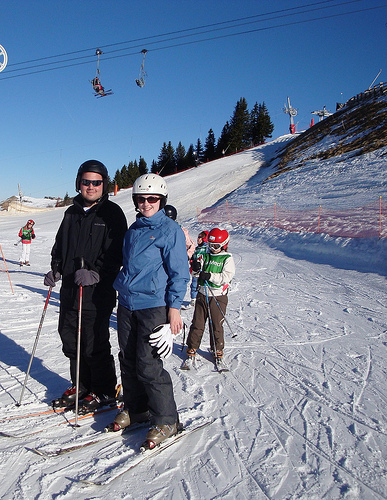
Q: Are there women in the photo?
A: Yes, there is a woman.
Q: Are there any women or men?
A: Yes, there is a woman.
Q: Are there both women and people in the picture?
A: Yes, there are both a woman and a person.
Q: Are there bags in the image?
A: No, there are no bags.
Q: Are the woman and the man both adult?
A: Yes, both the woman and the man are adult.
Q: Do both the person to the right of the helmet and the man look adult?
A: Yes, both the woman and the man are adult.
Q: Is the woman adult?
A: Yes, the woman is adult.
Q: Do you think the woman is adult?
A: Yes, the woman is adult.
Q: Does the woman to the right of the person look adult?
A: Yes, the woman is adult.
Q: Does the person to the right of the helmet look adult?
A: Yes, the woman is adult.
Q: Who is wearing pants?
A: The woman is wearing pants.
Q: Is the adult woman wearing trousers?
A: Yes, the woman is wearing trousers.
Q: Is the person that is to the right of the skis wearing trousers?
A: Yes, the woman is wearing trousers.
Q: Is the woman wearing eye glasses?
A: No, the woman is wearing trousers.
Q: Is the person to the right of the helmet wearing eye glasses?
A: No, the woman is wearing trousers.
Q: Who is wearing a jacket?
A: The woman is wearing a jacket.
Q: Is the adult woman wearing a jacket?
A: Yes, the woman is wearing a jacket.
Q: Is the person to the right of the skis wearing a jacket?
A: Yes, the woman is wearing a jacket.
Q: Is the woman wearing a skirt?
A: No, the woman is wearing a jacket.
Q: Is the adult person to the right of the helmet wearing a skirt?
A: No, the woman is wearing a jacket.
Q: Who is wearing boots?
A: The woman is wearing boots.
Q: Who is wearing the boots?
A: The woman is wearing boots.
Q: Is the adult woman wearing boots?
A: Yes, the woman is wearing boots.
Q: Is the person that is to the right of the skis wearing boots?
A: Yes, the woman is wearing boots.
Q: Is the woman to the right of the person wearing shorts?
A: No, the woman is wearing boots.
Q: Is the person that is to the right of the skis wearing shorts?
A: No, the woman is wearing boots.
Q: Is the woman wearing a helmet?
A: Yes, the woman is wearing a helmet.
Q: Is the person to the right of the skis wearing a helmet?
A: Yes, the woman is wearing a helmet.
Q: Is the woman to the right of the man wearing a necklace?
A: No, the woman is wearing a helmet.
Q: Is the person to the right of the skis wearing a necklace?
A: No, the woman is wearing a helmet.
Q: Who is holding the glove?
A: The woman is holding the glove.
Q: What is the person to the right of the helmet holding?
A: The woman is holding the glove.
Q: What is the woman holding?
A: The woman is holding the glove.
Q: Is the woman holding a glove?
A: Yes, the woman is holding a glove.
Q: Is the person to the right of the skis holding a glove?
A: Yes, the woman is holding a glove.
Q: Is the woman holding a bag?
A: No, the woman is holding a glove.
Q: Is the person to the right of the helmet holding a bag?
A: No, the woman is holding a glove.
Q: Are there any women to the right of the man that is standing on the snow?
A: Yes, there is a woman to the right of the man.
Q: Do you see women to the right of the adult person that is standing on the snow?
A: Yes, there is a woman to the right of the man.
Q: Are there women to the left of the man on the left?
A: No, the woman is to the right of the man.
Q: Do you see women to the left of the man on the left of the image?
A: No, the woman is to the right of the man.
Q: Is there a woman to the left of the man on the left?
A: No, the woman is to the right of the man.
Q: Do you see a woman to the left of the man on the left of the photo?
A: No, the woman is to the right of the man.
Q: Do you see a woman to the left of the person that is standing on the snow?
A: No, the woman is to the right of the man.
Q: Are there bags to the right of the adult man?
A: No, there is a woman to the right of the man.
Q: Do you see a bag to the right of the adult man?
A: No, there is a woman to the right of the man.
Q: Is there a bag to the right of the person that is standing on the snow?
A: No, there is a woman to the right of the man.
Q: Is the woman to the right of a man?
A: Yes, the woman is to the right of a man.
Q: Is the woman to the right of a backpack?
A: No, the woman is to the right of a man.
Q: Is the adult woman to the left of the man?
A: No, the woman is to the right of the man.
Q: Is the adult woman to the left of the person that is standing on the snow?
A: No, the woman is to the right of the man.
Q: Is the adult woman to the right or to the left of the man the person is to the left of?
A: The woman is to the right of the man.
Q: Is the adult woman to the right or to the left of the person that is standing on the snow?
A: The woman is to the right of the man.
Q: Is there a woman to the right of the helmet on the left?
A: Yes, there is a woman to the right of the helmet.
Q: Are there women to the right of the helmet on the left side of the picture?
A: Yes, there is a woman to the right of the helmet.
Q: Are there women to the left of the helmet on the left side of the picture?
A: No, the woman is to the right of the helmet.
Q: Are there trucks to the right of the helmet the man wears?
A: No, there is a woman to the right of the helmet.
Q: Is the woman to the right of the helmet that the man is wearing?
A: Yes, the woman is to the right of the helmet.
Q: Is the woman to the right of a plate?
A: No, the woman is to the right of the helmet.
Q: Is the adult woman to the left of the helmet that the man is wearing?
A: No, the woman is to the right of the helmet.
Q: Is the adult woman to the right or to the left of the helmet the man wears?
A: The woman is to the right of the helmet.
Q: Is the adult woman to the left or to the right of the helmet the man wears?
A: The woman is to the right of the helmet.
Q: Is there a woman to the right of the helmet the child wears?
A: No, the woman is to the left of the helmet.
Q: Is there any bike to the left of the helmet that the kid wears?
A: No, there is a woman to the left of the helmet.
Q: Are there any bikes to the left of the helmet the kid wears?
A: No, there is a woman to the left of the helmet.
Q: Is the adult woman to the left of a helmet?
A: Yes, the woman is to the left of a helmet.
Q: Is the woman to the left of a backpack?
A: No, the woman is to the left of a helmet.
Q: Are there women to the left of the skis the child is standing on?
A: Yes, there is a woman to the left of the skis.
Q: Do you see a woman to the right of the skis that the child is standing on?
A: No, the woman is to the left of the skis.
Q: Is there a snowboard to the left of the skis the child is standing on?
A: No, there is a woman to the left of the skis.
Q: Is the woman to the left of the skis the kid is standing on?
A: Yes, the woman is to the left of the skis.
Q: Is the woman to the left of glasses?
A: No, the woman is to the left of the skis.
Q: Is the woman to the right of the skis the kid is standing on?
A: No, the woman is to the left of the skis.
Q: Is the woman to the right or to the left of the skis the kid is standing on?
A: The woman is to the left of the skis.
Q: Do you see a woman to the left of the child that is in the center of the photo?
A: Yes, there is a woman to the left of the child.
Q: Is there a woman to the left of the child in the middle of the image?
A: Yes, there is a woman to the left of the child.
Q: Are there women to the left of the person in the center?
A: Yes, there is a woman to the left of the child.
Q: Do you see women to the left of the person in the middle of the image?
A: Yes, there is a woman to the left of the child.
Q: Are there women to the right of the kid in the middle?
A: No, the woman is to the left of the child.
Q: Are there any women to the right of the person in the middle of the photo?
A: No, the woman is to the left of the child.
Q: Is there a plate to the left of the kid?
A: No, there is a woman to the left of the kid.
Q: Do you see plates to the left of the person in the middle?
A: No, there is a woman to the left of the kid.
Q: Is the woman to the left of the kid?
A: Yes, the woman is to the left of the kid.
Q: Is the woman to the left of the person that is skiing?
A: Yes, the woman is to the left of the kid.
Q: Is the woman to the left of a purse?
A: No, the woman is to the left of the kid.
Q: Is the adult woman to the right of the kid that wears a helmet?
A: No, the woman is to the left of the kid.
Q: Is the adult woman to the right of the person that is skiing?
A: No, the woman is to the left of the kid.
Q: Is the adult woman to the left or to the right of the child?
A: The woman is to the left of the child.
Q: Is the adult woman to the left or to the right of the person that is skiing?
A: The woman is to the left of the child.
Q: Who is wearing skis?
A: The woman is wearing skis.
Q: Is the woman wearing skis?
A: Yes, the woman is wearing skis.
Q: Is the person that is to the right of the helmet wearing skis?
A: Yes, the woman is wearing skis.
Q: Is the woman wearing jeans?
A: No, the woman is wearing skis.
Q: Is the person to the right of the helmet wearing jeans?
A: No, the woman is wearing skis.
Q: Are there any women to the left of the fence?
A: Yes, there is a woman to the left of the fence.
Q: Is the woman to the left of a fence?
A: Yes, the woman is to the left of a fence.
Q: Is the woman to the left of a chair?
A: No, the woman is to the left of a fence.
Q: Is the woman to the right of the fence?
A: No, the woman is to the left of the fence.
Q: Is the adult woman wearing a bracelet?
A: No, the woman is wearing a helmet.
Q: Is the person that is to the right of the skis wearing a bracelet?
A: No, the woman is wearing a helmet.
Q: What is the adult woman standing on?
A: The woman is standing on the skis.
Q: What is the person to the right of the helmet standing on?
A: The woman is standing on the skis.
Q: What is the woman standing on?
A: The woman is standing on the skis.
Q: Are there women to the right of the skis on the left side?
A: Yes, there is a woman to the right of the skis.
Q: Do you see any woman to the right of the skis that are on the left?
A: Yes, there is a woman to the right of the skis.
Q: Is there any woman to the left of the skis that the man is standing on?
A: No, the woman is to the right of the skis.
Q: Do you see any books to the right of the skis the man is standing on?
A: No, there is a woman to the right of the skis.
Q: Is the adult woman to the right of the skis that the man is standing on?
A: Yes, the woman is to the right of the skis.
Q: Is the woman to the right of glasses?
A: No, the woman is to the right of the skis.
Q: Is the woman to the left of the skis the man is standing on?
A: No, the woman is to the right of the skis.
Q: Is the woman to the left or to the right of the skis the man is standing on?
A: The woman is to the right of the skis.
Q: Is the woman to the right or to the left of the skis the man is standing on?
A: The woman is to the right of the skis.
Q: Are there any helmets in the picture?
A: Yes, there is a helmet.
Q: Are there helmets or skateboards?
A: Yes, there is a helmet.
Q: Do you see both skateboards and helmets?
A: No, there is a helmet but no skateboards.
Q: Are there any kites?
A: No, there are no kites.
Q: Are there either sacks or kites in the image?
A: No, there are no kites or sacks.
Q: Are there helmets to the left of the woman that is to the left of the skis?
A: Yes, there is a helmet to the left of the woman.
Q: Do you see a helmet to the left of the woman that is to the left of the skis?
A: Yes, there is a helmet to the left of the woman.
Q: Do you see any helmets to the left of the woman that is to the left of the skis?
A: Yes, there is a helmet to the left of the woman.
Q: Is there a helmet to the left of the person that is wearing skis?
A: Yes, there is a helmet to the left of the woman.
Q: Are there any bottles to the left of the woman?
A: No, there is a helmet to the left of the woman.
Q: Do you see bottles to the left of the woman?
A: No, there is a helmet to the left of the woman.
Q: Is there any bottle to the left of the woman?
A: No, there is a helmet to the left of the woman.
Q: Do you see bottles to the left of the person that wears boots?
A: No, there is a helmet to the left of the woman.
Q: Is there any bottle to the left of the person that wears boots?
A: No, there is a helmet to the left of the woman.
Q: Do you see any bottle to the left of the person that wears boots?
A: No, there is a helmet to the left of the woman.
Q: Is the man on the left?
A: Yes, the man is on the left of the image.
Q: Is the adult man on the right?
A: No, the man is on the left of the image.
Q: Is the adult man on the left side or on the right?
A: The man is on the left of the image.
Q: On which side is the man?
A: The man is on the left of the image.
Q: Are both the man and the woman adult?
A: Yes, both the man and the woman are adult.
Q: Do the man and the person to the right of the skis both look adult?
A: Yes, both the man and the woman are adult.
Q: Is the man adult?
A: Yes, the man is adult.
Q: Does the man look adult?
A: Yes, the man is adult.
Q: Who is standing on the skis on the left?
A: The man is standing on the skis.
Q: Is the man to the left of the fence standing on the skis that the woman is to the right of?
A: Yes, the man is standing on the skis.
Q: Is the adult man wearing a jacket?
A: Yes, the man is wearing a jacket.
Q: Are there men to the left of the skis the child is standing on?
A: Yes, there is a man to the left of the skis.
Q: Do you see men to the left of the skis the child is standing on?
A: Yes, there is a man to the left of the skis.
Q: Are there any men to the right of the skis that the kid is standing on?
A: No, the man is to the left of the skis.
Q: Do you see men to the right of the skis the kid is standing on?
A: No, the man is to the left of the skis.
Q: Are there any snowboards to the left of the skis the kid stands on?
A: No, there is a man to the left of the skis.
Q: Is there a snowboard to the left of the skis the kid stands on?
A: No, there is a man to the left of the skis.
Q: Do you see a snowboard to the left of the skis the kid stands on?
A: No, there is a man to the left of the skis.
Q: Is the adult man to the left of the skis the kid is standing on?
A: Yes, the man is to the left of the skis.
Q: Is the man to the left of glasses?
A: No, the man is to the left of the skis.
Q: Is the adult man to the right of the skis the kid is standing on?
A: No, the man is to the left of the skis.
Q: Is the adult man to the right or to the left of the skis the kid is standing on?
A: The man is to the left of the skis.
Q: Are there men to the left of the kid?
A: Yes, there is a man to the left of the kid.